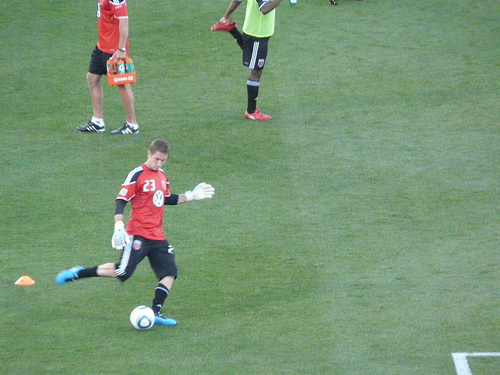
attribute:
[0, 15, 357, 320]
men — playing soccer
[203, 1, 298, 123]
man — stretching